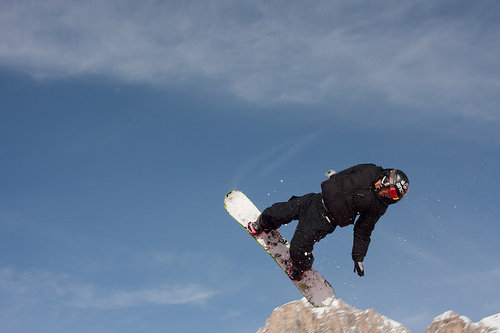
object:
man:
[248, 162, 409, 277]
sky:
[0, 0, 499, 332]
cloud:
[0, 3, 499, 107]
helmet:
[385, 167, 410, 201]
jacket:
[320, 163, 388, 264]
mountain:
[258, 298, 497, 332]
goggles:
[387, 178, 402, 201]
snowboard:
[223, 191, 335, 308]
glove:
[352, 259, 366, 276]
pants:
[260, 194, 336, 269]